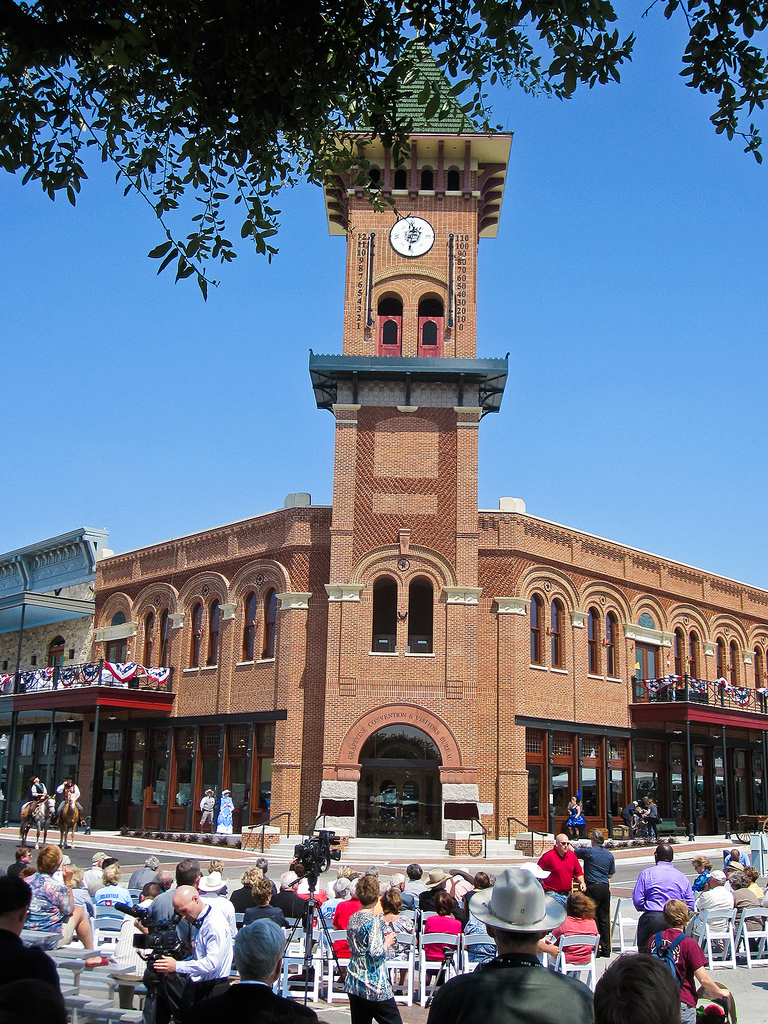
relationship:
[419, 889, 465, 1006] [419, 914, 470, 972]
person wearing shirt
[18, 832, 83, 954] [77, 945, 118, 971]
woman wearing shoes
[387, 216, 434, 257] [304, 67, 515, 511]
clock on tower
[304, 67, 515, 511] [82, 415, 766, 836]
tower on building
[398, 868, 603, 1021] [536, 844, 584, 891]
man wearing red shirt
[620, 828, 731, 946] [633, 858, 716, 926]
man wearing shirt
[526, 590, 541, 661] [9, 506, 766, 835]
window on building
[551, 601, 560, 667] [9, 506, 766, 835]
window on building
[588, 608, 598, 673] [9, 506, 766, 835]
window on building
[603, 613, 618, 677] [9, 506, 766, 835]
window on building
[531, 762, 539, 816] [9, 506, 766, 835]
window on building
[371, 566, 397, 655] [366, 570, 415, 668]
window on building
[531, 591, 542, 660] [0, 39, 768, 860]
window on brick building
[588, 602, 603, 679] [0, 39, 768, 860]
window on brick building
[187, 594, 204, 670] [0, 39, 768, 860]
window on brick building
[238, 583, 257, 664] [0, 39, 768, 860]
window on brick building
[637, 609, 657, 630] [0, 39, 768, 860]
window on brick building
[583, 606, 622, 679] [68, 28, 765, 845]
window on building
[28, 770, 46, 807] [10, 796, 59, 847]
person on horse